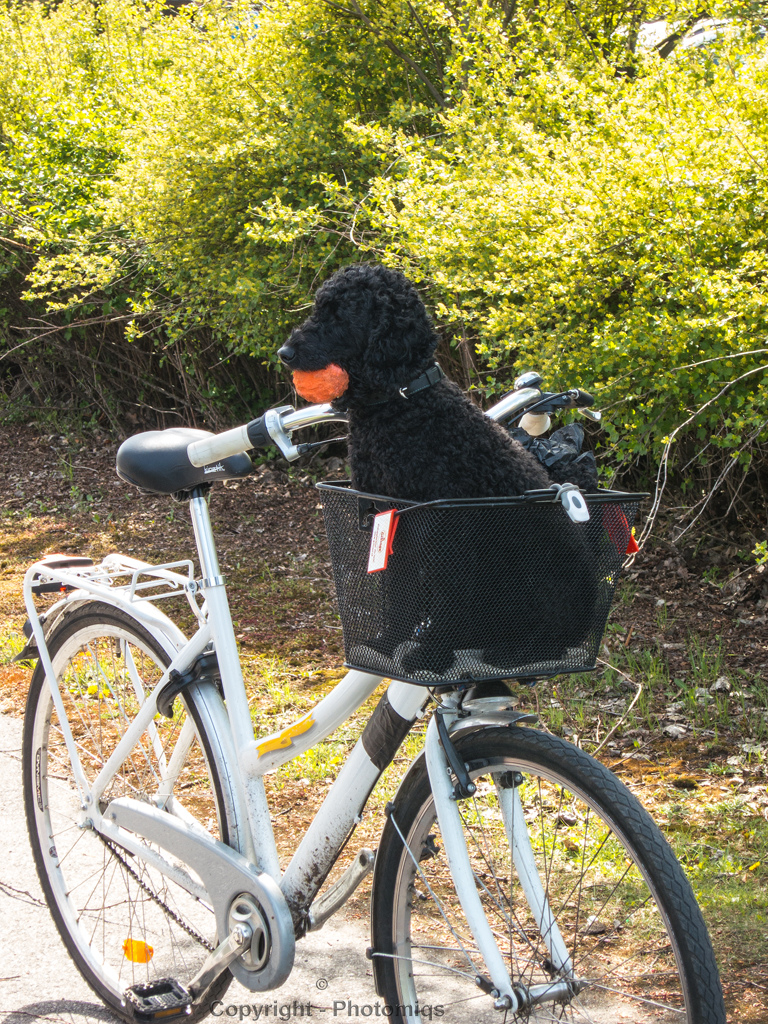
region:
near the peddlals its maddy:
[269, 719, 377, 930]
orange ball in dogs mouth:
[283, 356, 357, 407]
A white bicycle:
[15, 412, 651, 1019]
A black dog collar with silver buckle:
[357, 372, 452, 415]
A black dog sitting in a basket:
[241, 231, 687, 681]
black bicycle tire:
[376, 702, 712, 1022]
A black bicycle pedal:
[110, 963, 218, 1022]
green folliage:
[110, 29, 608, 262]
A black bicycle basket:
[309, 480, 673, 690]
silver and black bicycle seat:
[95, 404, 285, 582]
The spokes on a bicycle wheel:
[529, 795, 650, 993]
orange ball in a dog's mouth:
[285, 351, 356, 413]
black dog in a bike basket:
[255, 257, 659, 703]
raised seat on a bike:
[108, 396, 270, 609]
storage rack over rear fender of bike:
[19, 531, 225, 630]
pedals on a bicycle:
[123, 840, 449, 1021]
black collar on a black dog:
[334, 352, 463, 445]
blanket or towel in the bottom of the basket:
[343, 635, 600, 689]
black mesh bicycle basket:
[301, 468, 665, 705]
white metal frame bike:
[19, 562, 757, 1021]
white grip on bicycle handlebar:
[169, 405, 306, 483]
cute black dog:
[256, 251, 616, 648]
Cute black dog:
[273, 261, 658, 673]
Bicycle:
[13, 456, 739, 1005]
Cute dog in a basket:
[253, 265, 651, 675]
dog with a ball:
[266, 223, 482, 417]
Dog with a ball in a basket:
[17, 272, 747, 1018]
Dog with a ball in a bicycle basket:
[36, 258, 700, 1008]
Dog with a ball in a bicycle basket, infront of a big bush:
[12, 119, 756, 1007]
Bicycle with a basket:
[2, 470, 731, 976]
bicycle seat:
[110, 412, 253, 566]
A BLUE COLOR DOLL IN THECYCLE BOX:
[241, 259, 549, 499]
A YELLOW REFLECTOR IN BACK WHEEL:
[105, 926, 185, 976]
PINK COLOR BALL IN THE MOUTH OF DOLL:
[262, 261, 406, 413]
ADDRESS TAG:
[351, 496, 429, 583]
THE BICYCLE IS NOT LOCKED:
[127, 609, 267, 749]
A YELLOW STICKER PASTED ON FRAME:
[243, 704, 336, 768]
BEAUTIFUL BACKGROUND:
[20, 117, 673, 483]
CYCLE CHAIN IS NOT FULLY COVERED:
[56, 787, 307, 997]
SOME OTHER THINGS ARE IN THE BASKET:
[494, 365, 650, 527]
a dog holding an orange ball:
[268, 343, 411, 421]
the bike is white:
[26, 375, 687, 1005]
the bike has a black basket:
[323, 479, 655, 681]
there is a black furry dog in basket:
[249, 225, 616, 679]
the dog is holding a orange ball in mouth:
[283, 367, 353, 402]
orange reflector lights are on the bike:
[117, 937, 161, 972]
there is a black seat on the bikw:
[105, 415, 258, 507]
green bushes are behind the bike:
[0, 15, 750, 360]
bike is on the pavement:
[2, 756, 469, 1019]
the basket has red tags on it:
[348, 506, 405, 578]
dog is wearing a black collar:
[367, 365, 447, 418]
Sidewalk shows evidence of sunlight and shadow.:
[13, 761, 285, 1023]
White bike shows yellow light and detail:
[19, 579, 633, 1020]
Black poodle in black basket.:
[280, 265, 603, 665]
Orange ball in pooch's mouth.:
[272, 359, 352, 423]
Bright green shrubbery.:
[400, 85, 721, 282]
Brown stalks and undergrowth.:
[18, 309, 202, 414]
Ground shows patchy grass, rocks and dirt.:
[76, 450, 749, 1006]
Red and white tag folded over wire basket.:
[362, 492, 414, 601]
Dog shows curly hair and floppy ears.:
[328, 257, 496, 485]